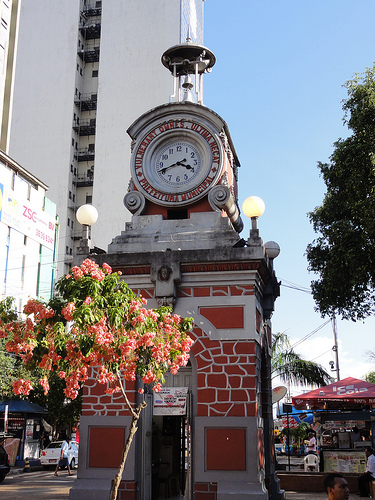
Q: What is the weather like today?
A: It is clear.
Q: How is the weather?
A: It is clear.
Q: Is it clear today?
A: Yes, it is clear.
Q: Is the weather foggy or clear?
A: It is clear.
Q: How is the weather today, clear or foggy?
A: It is clear.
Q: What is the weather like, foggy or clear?
A: It is clear.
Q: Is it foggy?
A: No, it is clear.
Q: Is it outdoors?
A: Yes, it is outdoors.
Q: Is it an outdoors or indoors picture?
A: It is outdoors.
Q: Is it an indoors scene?
A: No, it is outdoors.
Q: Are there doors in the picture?
A: Yes, there is a door.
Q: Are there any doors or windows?
A: Yes, there is a door.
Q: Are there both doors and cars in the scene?
A: Yes, there are both a door and a car.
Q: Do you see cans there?
A: No, there are no cans.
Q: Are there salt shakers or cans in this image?
A: No, there are no cans or salt shakers.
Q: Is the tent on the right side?
A: Yes, the tent is on the right of the image.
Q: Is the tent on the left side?
A: No, the tent is on the right of the image.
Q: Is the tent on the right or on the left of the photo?
A: The tent is on the right of the image.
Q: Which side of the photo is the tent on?
A: The tent is on the right of the image.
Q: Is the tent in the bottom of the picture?
A: Yes, the tent is in the bottom of the image.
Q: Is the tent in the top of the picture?
A: No, the tent is in the bottom of the image.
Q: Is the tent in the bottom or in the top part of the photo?
A: The tent is in the bottom of the image.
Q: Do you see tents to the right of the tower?
A: Yes, there is a tent to the right of the tower.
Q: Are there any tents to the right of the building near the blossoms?
A: Yes, there is a tent to the right of the tower.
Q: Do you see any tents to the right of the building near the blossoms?
A: Yes, there is a tent to the right of the tower.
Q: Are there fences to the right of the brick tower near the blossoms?
A: No, there is a tent to the right of the tower.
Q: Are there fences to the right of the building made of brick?
A: No, there is a tent to the right of the tower.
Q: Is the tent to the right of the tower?
A: Yes, the tent is to the right of the tower.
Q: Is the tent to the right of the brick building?
A: Yes, the tent is to the right of the tower.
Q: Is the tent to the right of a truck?
A: No, the tent is to the right of the tower.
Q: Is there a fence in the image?
A: No, there are no fences.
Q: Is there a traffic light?
A: No, there are no traffic lights.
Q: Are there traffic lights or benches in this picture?
A: No, there are no traffic lights or benches.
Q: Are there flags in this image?
A: No, there are no flags.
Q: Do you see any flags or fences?
A: No, there are no flags or fences.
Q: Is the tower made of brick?
A: Yes, the tower is made of brick.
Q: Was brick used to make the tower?
A: Yes, the tower is made of brick.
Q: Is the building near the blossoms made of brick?
A: Yes, the tower is made of brick.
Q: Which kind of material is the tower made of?
A: The tower is made of brick.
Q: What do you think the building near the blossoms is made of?
A: The tower is made of brick.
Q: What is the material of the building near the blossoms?
A: The tower is made of brick.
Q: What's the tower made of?
A: The tower is made of brick.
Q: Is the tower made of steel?
A: No, the tower is made of brick.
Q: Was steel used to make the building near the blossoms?
A: No, the tower is made of brick.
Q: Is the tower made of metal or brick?
A: The tower is made of brick.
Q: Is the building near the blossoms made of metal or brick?
A: The tower is made of brick.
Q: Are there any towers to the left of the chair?
A: Yes, there is a tower to the left of the chair.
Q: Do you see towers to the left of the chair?
A: Yes, there is a tower to the left of the chair.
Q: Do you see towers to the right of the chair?
A: No, the tower is to the left of the chair.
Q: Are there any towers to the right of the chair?
A: No, the tower is to the left of the chair.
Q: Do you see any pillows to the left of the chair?
A: No, there is a tower to the left of the chair.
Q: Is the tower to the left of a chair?
A: Yes, the tower is to the left of a chair.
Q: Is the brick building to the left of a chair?
A: Yes, the tower is to the left of a chair.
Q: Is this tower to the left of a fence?
A: No, the tower is to the left of a chair.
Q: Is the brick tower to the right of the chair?
A: No, the tower is to the left of the chair.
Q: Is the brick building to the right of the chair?
A: No, the tower is to the left of the chair.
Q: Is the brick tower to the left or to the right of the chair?
A: The tower is to the left of the chair.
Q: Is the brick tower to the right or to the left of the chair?
A: The tower is to the left of the chair.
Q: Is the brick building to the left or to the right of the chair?
A: The tower is to the left of the chair.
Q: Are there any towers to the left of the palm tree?
A: Yes, there is a tower to the left of the palm tree.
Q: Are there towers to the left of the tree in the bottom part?
A: Yes, there is a tower to the left of the palm tree.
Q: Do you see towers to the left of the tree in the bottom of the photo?
A: Yes, there is a tower to the left of the palm tree.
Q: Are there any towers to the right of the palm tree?
A: No, the tower is to the left of the palm tree.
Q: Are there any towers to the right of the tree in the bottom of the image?
A: No, the tower is to the left of the palm tree.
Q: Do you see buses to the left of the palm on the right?
A: No, there is a tower to the left of the palm tree.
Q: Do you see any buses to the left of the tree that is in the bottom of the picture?
A: No, there is a tower to the left of the palm tree.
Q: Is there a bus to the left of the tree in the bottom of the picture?
A: No, there is a tower to the left of the palm tree.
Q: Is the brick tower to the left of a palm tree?
A: Yes, the tower is to the left of a palm tree.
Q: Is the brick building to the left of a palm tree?
A: Yes, the tower is to the left of a palm tree.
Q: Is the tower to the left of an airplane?
A: No, the tower is to the left of a palm tree.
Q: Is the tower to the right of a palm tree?
A: No, the tower is to the left of a palm tree.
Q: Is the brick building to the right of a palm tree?
A: No, the tower is to the left of a palm tree.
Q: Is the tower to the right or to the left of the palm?
A: The tower is to the left of the palm.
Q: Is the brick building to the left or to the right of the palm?
A: The tower is to the left of the palm.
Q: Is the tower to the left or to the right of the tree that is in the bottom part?
A: The tower is to the left of the palm.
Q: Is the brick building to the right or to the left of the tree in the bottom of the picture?
A: The tower is to the left of the palm.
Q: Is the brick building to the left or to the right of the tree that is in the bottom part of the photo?
A: The tower is to the left of the palm.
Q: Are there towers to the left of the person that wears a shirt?
A: Yes, there is a tower to the left of the person.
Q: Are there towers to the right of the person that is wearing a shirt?
A: No, the tower is to the left of the person.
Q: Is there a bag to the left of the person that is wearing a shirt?
A: No, there is a tower to the left of the person.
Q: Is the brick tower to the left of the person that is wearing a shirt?
A: Yes, the tower is to the left of the person.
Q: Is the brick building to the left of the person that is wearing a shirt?
A: Yes, the tower is to the left of the person.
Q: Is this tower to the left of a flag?
A: No, the tower is to the left of the person.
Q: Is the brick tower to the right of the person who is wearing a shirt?
A: No, the tower is to the left of the person.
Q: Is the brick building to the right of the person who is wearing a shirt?
A: No, the tower is to the left of the person.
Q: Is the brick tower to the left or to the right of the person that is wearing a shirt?
A: The tower is to the left of the person.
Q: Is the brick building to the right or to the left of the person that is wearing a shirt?
A: The tower is to the left of the person.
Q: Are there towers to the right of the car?
A: Yes, there is a tower to the right of the car.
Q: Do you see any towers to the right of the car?
A: Yes, there is a tower to the right of the car.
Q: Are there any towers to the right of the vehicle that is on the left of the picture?
A: Yes, there is a tower to the right of the car.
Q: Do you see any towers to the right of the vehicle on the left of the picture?
A: Yes, there is a tower to the right of the car.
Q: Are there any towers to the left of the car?
A: No, the tower is to the right of the car.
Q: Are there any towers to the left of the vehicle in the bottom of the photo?
A: No, the tower is to the right of the car.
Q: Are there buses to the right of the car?
A: No, there is a tower to the right of the car.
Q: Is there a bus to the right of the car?
A: No, there is a tower to the right of the car.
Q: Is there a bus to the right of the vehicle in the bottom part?
A: No, there is a tower to the right of the car.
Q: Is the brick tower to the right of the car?
A: Yes, the tower is to the right of the car.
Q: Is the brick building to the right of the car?
A: Yes, the tower is to the right of the car.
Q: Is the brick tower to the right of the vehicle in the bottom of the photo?
A: Yes, the tower is to the right of the car.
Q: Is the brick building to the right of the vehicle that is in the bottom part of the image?
A: Yes, the tower is to the right of the car.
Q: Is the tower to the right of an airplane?
A: No, the tower is to the right of the car.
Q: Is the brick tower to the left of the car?
A: No, the tower is to the right of the car.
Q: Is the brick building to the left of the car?
A: No, the tower is to the right of the car.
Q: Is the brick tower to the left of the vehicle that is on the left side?
A: No, the tower is to the right of the car.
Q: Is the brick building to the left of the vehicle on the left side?
A: No, the tower is to the right of the car.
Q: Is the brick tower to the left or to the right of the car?
A: The tower is to the right of the car.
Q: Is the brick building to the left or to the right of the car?
A: The tower is to the right of the car.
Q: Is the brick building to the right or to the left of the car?
A: The tower is to the right of the car.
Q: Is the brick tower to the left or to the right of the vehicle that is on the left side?
A: The tower is to the right of the car.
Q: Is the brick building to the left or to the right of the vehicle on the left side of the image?
A: The tower is to the right of the car.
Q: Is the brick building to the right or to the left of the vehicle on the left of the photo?
A: The tower is to the right of the car.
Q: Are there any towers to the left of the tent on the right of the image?
A: Yes, there is a tower to the left of the tent.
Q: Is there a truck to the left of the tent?
A: No, there is a tower to the left of the tent.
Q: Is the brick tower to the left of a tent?
A: Yes, the tower is to the left of a tent.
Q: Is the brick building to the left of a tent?
A: Yes, the tower is to the left of a tent.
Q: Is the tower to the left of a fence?
A: No, the tower is to the left of a tent.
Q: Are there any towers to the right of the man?
A: Yes, there is a tower to the right of the man.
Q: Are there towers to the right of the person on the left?
A: Yes, there is a tower to the right of the man.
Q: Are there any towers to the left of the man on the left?
A: No, the tower is to the right of the man.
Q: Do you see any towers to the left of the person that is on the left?
A: No, the tower is to the right of the man.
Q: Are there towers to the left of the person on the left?
A: No, the tower is to the right of the man.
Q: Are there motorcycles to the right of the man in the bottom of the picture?
A: No, there is a tower to the right of the man.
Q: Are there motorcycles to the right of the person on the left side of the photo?
A: No, there is a tower to the right of the man.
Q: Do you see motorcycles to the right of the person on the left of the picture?
A: No, there is a tower to the right of the man.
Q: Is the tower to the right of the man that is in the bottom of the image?
A: Yes, the tower is to the right of the man.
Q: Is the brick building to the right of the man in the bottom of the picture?
A: Yes, the tower is to the right of the man.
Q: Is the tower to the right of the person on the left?
A: Yes, the tower is to the right of the man.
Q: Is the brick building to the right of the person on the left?
A: Yes, the tower is to the right of the man.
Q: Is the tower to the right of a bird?
A: No, the tower is to the right of the man.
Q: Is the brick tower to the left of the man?
A: No, the tower is to the right of the man.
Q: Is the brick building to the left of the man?
A: No, the tower is to the right of the man.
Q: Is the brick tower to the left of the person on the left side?
A: No, the tower is to the right of the man.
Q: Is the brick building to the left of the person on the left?
A: No, the tower is to the right of the man.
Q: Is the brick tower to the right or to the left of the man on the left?
A: The tower is to the right of the man.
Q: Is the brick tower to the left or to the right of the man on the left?
A: The tower is to the right of the man.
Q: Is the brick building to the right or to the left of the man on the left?
A: The tower is to the right of the man.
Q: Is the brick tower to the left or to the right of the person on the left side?
A: The tower is to the right of the man.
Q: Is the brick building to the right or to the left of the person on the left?
A: The tower is to the right of the man.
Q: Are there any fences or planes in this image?
A: No, there are no fences or planes.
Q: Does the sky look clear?
A: Yes, the sky is clear.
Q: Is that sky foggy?
A: No, the sky is clear.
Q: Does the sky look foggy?
A: No, the sky is clear.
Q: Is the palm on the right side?
A: Yes, the palm is on the right of the image.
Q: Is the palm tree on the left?
A: No, the palm tree is on the right of the image.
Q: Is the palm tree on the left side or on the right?
A: The palm tree is on the right of the image.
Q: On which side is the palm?
A: The palm is on the right of the image.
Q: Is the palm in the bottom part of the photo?
A: Yes, the palm is in the bottom of the image.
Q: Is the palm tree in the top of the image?
A: No, the palm tree is in the bottom of the image.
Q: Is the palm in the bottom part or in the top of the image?
A: The palm is in the bottom of the image.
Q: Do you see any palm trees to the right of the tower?
A: Yes, there is a palm tree to the right of the tower.